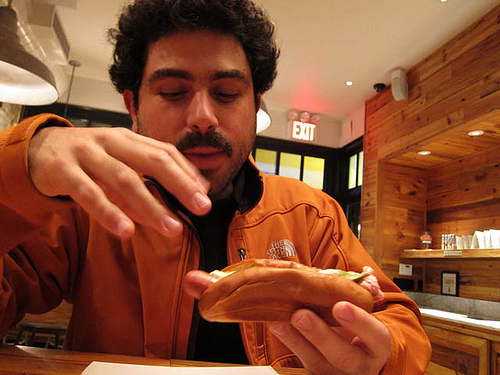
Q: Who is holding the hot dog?
A: The man.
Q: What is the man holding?
A: A hot dog.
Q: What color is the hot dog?
A: Pink and brown.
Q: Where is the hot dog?
A: In the man's hand.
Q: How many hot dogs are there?
A: One.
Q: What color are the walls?
A: Brown.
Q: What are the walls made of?
A: Wood.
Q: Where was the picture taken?
A: In a restaurant.